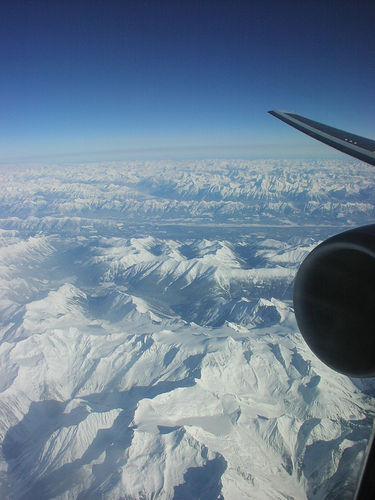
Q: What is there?
A: Mountains.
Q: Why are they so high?
A: Flying.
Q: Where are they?
A: Airplane.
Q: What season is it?
A: Winter.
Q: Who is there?
A: No one.